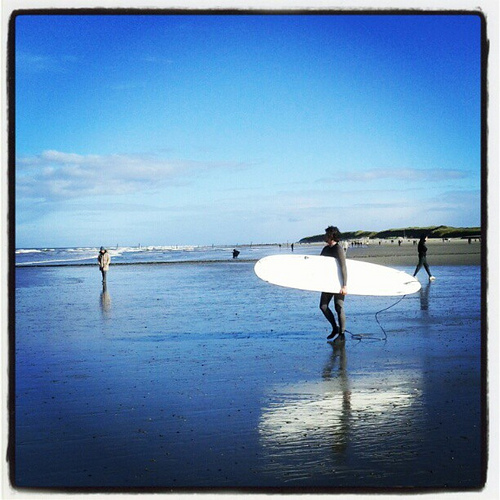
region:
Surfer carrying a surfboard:
[250, 223, 425, 351]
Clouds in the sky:
[15, 144, 480, 231]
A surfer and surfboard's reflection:
[255, 378, 424, 474]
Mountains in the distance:
[300, 227, 491, 242]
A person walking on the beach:
[403, 234, 438, 284]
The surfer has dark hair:
[320, 225, 343, 243]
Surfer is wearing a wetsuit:
[316, 244, 352, 343]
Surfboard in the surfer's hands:
[252, 250, 421, 298]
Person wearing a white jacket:
[92, 245, 114, 289]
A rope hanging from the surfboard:
[343, 282, 417, 348]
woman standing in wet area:
[89, 245, 119, 288]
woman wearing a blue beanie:
[93, 242, 115, 290]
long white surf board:
[247, 242, 432, 301]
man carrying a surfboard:
[257, 218, 419, 348]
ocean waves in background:
[18, 242, 218, 262]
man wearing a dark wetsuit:
[314, 217, 356, 345]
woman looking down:
[86, 242, 123, 292]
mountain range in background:
[305, 223, 479, 243]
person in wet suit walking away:
[407, 231, 444, 290]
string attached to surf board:
[348, 288, 413, 355]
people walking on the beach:
[250, 205, 456, 371]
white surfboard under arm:
[248, 249, 425, 307]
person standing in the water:
[86, 244, 116, 306]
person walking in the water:
[406, 228, 438, 288]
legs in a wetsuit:
[312, 295, 352, 331]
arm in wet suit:
[327, 250, 355, 292]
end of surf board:
[393, 265, 440, 305]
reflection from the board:
[301, 426, 337, 450]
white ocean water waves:
[63, 253, 83, 261]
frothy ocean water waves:
[126, 243, 143, 257]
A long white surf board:
[252, 253, 421, 295]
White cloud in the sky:
[15, 149, 272, 220]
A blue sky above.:
[14, 15, 477, 247]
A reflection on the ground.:
[257, 357, 428, 479]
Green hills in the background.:
[291, 223, 479, 241]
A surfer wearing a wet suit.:
[318, 225, 348, 340]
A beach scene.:
[14, 242, 484, 489]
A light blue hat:
[100, 245, 104, 251]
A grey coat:
[96, 250, 110, 272]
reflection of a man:
[98, 288, 112, 314]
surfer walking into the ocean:
[237, 218, 423, 338]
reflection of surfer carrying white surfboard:
[255, 361, 402, 456]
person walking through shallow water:
[86, 233, 116, 280]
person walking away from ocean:
[400, 235, 447, 278]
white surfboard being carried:
[252, 248, 419, 297]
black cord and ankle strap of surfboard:
[335, 293, 403, 343]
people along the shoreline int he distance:
[220, 238, 461, 258]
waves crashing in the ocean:
[28, 235, 193, 265]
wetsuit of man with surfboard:
[314, 244, 361, 326]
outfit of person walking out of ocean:
[408, 237, 433, 271]